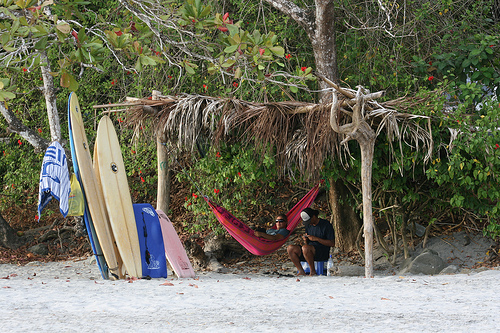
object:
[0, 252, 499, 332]
sand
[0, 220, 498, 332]
ground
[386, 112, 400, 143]
leaf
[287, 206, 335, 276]
person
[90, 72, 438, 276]
shack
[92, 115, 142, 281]
surfboard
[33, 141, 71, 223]
towel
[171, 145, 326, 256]
hammock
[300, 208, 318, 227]
hat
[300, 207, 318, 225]
head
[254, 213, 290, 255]
man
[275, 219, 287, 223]
sunglasses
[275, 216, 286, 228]
face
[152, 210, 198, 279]
boogie board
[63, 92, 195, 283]
group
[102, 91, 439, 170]
roof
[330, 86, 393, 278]
pole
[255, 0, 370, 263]
tree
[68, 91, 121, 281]
another surfboard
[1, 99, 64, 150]
branch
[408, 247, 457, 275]
stone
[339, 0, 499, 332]
right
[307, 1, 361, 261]
tree stem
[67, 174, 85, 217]
bag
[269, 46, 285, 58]
leaf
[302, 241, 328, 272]
leg